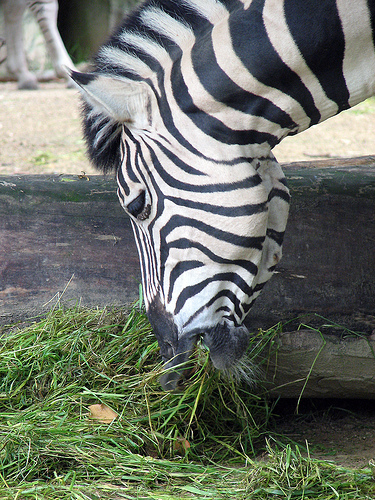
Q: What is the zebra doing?
A: Eating.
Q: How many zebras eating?
A: One.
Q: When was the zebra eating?
A: Daytime.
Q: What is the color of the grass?
A: Green.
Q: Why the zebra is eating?
A: It is hungry.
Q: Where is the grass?
A: On the ground.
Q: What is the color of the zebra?
A: Black and white.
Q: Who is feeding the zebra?
A: No one.